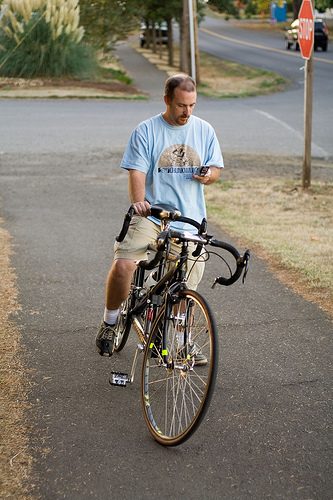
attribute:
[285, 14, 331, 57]
vehicle — black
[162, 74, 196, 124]
head — bare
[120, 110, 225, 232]
shirt — blue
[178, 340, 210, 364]
tennis shoe — beige, black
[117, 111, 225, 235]
t-shirt — blue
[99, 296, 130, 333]
socks — white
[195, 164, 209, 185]
cellphone — silver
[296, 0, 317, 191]
sign — stop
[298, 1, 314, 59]
stop sign — red and white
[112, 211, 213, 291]
shorts — beige